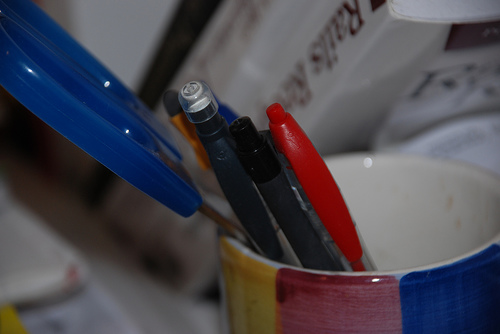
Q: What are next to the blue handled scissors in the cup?
A: Pens.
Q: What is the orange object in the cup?
A: A pen.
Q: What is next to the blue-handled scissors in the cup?
A: A grey pen with a clear top.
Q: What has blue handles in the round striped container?
A: Scissors.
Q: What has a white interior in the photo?
A: The container.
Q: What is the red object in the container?
A: A pen.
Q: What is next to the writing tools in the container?
A: A pair of blue handled scissors.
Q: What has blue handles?
A: Scissors.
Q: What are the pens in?
A: A cup.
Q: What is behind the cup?
A: Book.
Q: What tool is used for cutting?
A: Scissors.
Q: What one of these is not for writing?
A: Scissors.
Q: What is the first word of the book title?
A: Rails.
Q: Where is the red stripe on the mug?
A: Middle.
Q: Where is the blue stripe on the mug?
A: Right.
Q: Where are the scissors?
A: In the cup.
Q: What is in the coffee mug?
A: Scissors, pens and pencils.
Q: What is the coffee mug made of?
A: Ceramic.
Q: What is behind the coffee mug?
A: A book.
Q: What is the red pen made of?
A: Plastic.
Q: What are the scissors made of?
A: Metal and plastic.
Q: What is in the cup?
A: Pens and pencils.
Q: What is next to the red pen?
A: A black pen.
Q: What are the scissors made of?
A: Plastic and metal.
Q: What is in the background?
A: A white textbook.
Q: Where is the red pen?
A: In the cup.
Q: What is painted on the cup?
A: Three squares, red, yellow and blue.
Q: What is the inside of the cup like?
A: Painted white.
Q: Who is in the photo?
A: Nobody.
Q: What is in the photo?
A: Pens.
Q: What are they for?
A: Writing.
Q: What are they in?
A: A cup.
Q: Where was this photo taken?
A: At an office.